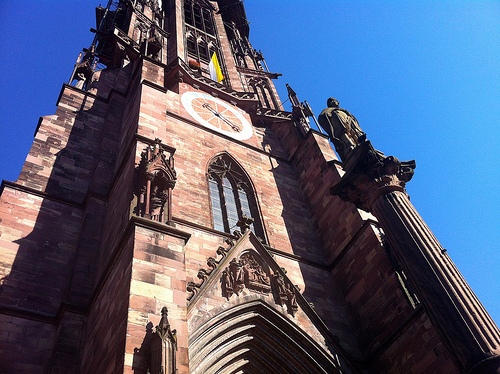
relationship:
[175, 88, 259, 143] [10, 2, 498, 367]
clock on tower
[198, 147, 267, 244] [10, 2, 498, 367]
window on tower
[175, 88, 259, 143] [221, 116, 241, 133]
clock has hand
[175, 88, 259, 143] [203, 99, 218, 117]
clock has hand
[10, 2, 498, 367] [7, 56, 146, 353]
tower has shadow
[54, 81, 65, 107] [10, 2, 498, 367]
mark on tower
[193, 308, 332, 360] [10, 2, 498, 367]
arch on tower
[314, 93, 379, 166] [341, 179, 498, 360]
statue on column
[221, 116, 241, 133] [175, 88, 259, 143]
hand on clock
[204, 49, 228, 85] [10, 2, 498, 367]
flag on tower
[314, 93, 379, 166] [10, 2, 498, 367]
statue on tower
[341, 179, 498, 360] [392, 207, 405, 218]
column has ridges